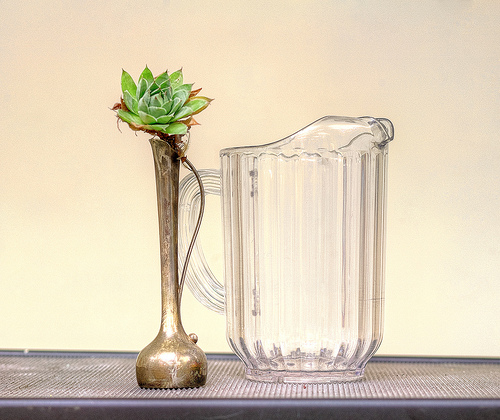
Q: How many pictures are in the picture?
A: One.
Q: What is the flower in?
A: A vase.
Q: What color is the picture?
A: Clear.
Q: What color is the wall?
A: White.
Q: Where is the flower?
A: In the vase.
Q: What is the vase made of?
A: Metal.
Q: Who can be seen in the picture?
A: No one.